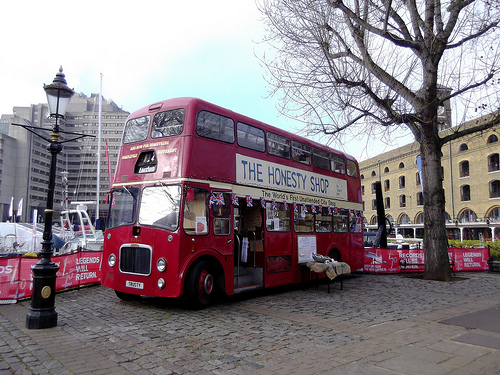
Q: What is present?
A: A bus.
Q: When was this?
A: Daytime.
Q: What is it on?
A: Wheels.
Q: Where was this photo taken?
A: The sidewalk.